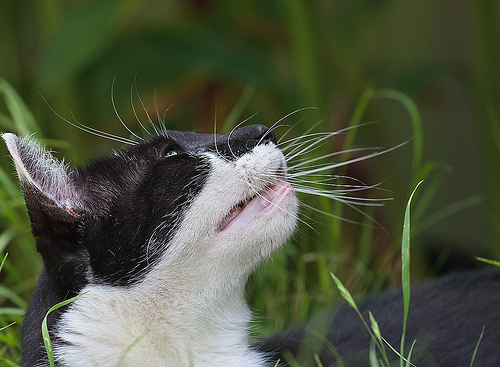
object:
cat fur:
[153, 285, 238, 314]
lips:
[259, 187, 296, 214]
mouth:
[218, 162, 297, 233]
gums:
[221, 181, 285, 231]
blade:
[399, 179, 424, 366]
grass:
[0, 80, 500, 367]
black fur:
[96, 212, 139, 249]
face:
[120, 123, 301, 283]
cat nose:
[237, 123, 277, 145]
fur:
[432, 299, 475, 324]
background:
[0, 0, 500, 367]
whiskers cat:
[213, 106, 417, 236]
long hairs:
[38, 72, 178, 147]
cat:
[7, 108, 301, 365]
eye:
[160, 144, 186, 158]